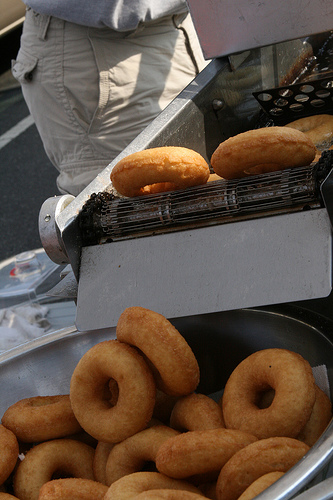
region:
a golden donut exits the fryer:
[113, 141, 207, 205]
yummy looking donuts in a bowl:
[5, 325, 204, 498]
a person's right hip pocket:
[10, 0, 126, 143]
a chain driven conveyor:
[88, 190, 310, 242]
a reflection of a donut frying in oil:
[207, 35, 283, 117]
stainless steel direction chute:
[94, 250, 329, 294]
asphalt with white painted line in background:
[4, 91, 25, 244]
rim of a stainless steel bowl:
[256, 308, 331, 342]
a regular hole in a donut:
[246, 370, 280, 412]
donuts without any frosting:
[52, 427, 247, 497]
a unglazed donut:
[107, 142, 211, 197]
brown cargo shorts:
[17, 17, 202, 194]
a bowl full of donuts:
[1, 302, 332, 498]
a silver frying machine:
[34, 63, 331, 334]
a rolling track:
[90, 163, 323, 236]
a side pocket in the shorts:
[53, 30, 116, 134]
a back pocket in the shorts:
[9, 45, 42, 86]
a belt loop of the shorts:
[37, 12, 51, 43]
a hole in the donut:
[247, 377, 277, 414]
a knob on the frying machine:
[9, 246, 45, 279]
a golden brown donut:
[109, 145, 210, 197]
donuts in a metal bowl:
[2, 305, 331, 497]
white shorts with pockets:
[10, 5, 212, 196]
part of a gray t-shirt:
[22, 2, 190, 34]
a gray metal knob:
[37, 193, 76, 265]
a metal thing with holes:
[251, 73, 329, 127]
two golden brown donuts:
[68, 303, 200, 444]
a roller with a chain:
[77, 148, 330, 247]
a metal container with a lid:
[1, 244, 66, 309]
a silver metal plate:
[73, 206, 330, 333]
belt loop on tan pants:
[31, 13, 55, 42]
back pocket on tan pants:
[12, 50, 54, 87]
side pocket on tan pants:
[67, 29, 107, 133]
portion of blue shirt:
[28, 0, 197, 34]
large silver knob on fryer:
[28, 188, 86, 260]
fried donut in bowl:
[122, 303, 197, 393]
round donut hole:
[89, 365, 126, 417]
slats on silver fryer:
[254, 76, 321, 105]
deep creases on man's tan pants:
[114, 47, 161, 108]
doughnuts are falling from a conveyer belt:
[87, 110, 331, 234]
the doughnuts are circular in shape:
[218, 346, 313, 435]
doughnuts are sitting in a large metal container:
[2, 306, 332, 499]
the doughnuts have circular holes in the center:
[88, 374, 120, 412]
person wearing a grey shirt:
[72, 2, 149, 27]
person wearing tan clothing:
[123, 44, 157, 84]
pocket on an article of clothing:
[62, 34, 119, 132]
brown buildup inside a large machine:
[284, 47, 312, 87]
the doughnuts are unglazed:
[162, 428, 236, 469]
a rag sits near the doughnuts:
[0, 304, 51, 347]